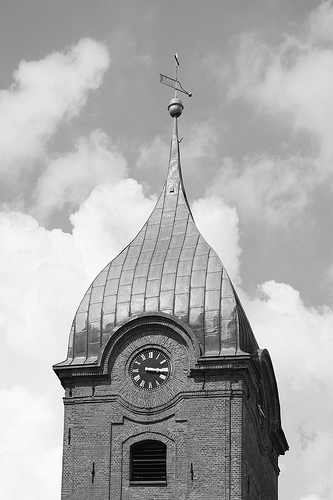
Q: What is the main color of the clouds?
A: White.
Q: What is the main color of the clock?
A: Black.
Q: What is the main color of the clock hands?
A: White.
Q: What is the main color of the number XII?
A: White.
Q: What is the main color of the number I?
A: White.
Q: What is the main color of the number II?
A: White.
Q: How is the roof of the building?
A: Metal.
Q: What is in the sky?
A: Clouds.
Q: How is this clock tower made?
A: With bricks.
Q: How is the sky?
A: Cloudy.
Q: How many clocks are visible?
A: Just one.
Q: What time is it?
A: 3:15.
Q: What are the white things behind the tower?
A: Clouds.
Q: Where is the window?
A: Below the clock.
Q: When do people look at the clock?
A: When they want to know what time it is.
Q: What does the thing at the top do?
A: Show which way the wind is blowing.